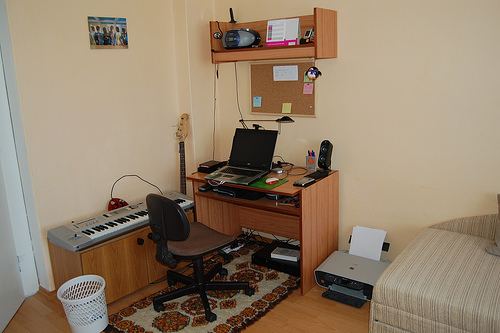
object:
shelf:
[209, 7, 337, 63]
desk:
[186, 157, 341, 296]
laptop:
[204, 127, 279, 184]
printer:
[315, 224, 393, 307]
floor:
[13, 239, 378, 332]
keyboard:
[48, 189, 194, 252]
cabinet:
[48, 209, 215, 306]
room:
[3, 0, 499, 333]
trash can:
[56, 273, 110, 332]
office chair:
[146, 191, 254, 322]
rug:
[102, 237, 300, 332]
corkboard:
[248, 59, 317, 116]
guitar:
[170, 111, 189, 198]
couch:
[367, 213, 499, 332]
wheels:
[203, 312, 219, 320]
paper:
[348, 223, 386, 261]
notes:
[273, 64, 298, 81]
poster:
[87, 15, 129, 50]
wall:
[7, 0, 179, 241]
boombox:
[221, 27, 260, 50]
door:
[0, 0, 42, 329]